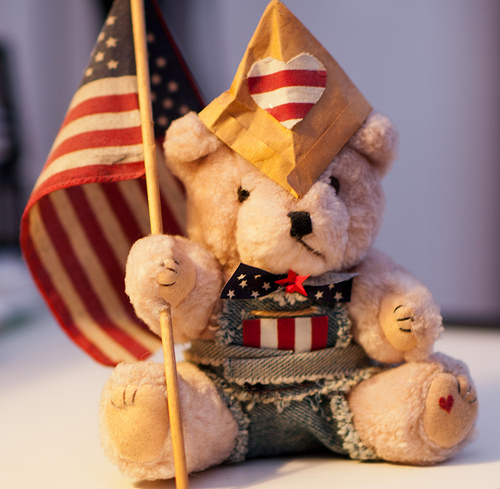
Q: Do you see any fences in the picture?
A: No, there are no fences.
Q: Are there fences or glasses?
A: No, there are no fences or glasses.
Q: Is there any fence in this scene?
A: No, there are no fences.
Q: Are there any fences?
A: No, there are no fences.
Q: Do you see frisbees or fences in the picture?
A: No, there are no fences or frisbees.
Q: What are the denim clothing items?
A: The clothing items are shorts.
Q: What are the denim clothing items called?
A: The clothing items are shorts.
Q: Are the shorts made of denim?
A: Yes, the shorts are made of denim.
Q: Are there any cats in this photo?
A: No, there are no cats.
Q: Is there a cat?
A: No, there are no cats.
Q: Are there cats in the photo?
A: No, there are no cats.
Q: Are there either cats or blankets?
A: No, there are no cats or blankets.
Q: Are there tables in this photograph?
A: Yes, there is a table.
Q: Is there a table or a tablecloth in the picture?
A: Yes, there is a table.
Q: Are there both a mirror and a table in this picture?
A: No, there is a table but no mirrors.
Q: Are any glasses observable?
A: No, there are no glasses.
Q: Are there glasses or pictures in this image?
A: No, there are no glasses or pictures.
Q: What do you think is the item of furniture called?
A: The piece of furniture is a table.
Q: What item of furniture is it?
A: The piece of furniture is a table.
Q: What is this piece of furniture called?
A: This is a table.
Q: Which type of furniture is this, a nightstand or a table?
A: This is a table.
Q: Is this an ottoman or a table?
A: This is a table.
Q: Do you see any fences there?
A: No, there are no fences.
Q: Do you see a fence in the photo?
A: No, there are no fences.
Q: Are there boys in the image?
A: No, there are no boys.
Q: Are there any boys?
A: No, there are no boys.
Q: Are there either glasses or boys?
A: No, there are no boys or glasses.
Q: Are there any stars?
A: Yes, there is a star.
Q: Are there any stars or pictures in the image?
A: Yes, there is a star.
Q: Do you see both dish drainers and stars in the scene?
A: No, there is a star but no dish drainers.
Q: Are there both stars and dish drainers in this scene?
A: No, there is a star but no dish drainers.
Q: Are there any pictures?
A: No, there are no pictures.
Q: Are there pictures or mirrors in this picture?
A: No, there are no pictures or mirrors.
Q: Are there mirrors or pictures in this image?
A: No, there are no pictures or mirrors.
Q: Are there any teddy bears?
A: Yes, there is a teddy bear.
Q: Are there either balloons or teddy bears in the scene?
A: Yes, there is a teddy bear.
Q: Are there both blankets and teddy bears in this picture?
A: No, there is a teddy bear but no blankets.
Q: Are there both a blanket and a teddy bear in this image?
A: No, there is a teddy bear but no blankets.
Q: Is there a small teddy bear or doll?
A: Yes, there is a small teddy bear.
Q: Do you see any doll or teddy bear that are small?
A: Yes, the teddy bear is small.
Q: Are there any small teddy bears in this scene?
A: Yes, there is a small teddy bear.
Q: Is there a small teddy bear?
A: Yes, there is a small teddy bear.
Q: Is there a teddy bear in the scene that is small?
A: Yes, there is a teddy bear that is small.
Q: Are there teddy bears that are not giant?
A: Yes, there is a small teddy bear.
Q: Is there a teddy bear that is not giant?
A: Yes, there is a small teddy bear.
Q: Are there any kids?
A: No, there are no kids.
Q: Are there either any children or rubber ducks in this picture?
A: No, there are no children or rubber ducks.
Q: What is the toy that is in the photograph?
A: The toy is a teddy bear.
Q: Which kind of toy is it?
A: The toy is a teddy bear.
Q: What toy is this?
A: This is a teddy bear.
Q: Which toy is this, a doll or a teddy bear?
A: This is a teddy bear.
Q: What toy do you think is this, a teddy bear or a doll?
A: This is a teddy bear.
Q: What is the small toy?
A: The toy is a teddy bear.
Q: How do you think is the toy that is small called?
A: The toy is a teddy bear.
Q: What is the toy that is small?
A: The toy is a teddy bear.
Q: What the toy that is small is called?
A: The toy is a teddy bear.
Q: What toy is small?
A: The toy is a teddy bear.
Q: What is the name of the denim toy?
A: The toy is a teddy bear.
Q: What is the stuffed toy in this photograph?
A: The toy is a teddy bear.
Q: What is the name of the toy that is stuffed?
A: The toy is a teddy bear.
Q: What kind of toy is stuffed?
A: The toy is a teddy bear.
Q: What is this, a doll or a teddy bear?
A: This is a teddy bear.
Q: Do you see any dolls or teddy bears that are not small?
A: No, there is a teddy bear but it is small.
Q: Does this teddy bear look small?
A: Yes, the teddy bear is small.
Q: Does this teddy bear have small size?
A: Yes, the teddy bear is small.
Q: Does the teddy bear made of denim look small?
A: Yes, the teddy bear is small.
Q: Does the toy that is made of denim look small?
A: Yes, the teddy bear is small.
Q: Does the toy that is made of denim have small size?
A: Yes, the teddy bear is small.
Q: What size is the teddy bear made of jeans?
A: The teddy bear is small.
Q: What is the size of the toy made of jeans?
A: The teddy bear is small.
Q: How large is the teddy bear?
A: The teddy bear is small.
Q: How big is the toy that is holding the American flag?
A: The teddy bear is small.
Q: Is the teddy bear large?
A: No, the teddy bear is small.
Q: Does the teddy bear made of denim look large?
A: No, the teddy bear is small.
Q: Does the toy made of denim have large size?
A: No, the teddy bear is small.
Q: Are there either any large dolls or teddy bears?
A: No, there is a teddy bear but it is small.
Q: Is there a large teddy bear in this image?
A: No, there is a teddy bear but it is small.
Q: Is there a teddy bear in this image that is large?
A: No, there is a teddy bear but it is small.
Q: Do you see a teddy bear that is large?
A: No, there is a teddy bear but it is small.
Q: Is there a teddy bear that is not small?
A: No, there is a teddy bear but it is small.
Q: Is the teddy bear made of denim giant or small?
A: The teddy bear is small.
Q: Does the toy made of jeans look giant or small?
A: The teddy bear is small.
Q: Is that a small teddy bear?
A: Yes, that is a small teddy bear.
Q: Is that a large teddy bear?
A: No, that is a small teddy bear.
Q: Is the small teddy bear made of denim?
A: Yes, the teddy bear is made of denim.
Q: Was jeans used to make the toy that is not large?
A: Yes, the teddy bear is made of jeans.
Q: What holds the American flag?
A: The teddy bear holds the American flag.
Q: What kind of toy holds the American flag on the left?
A: The toy is a teddy bear.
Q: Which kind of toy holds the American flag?
A: The toy is a teddy bear.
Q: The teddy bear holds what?
A: The teddy bear holds the American flag.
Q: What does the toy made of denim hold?
A: The teddy bear holds the American flag.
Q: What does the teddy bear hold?
A: The teddy bear holds the American flag.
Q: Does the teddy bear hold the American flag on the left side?
A: Yes, the teddy bear holds the American flag.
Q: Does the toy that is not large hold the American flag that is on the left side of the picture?
A: Yes, the teddy bear holds the American flag.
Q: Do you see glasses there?
A: No, there are no glasses.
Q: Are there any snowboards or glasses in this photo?
A: No, there are no glasses or snowboards.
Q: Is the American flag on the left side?
A: Yes, the American flag is on the left of the image.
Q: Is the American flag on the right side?
A: No, the American flag is on the left of the image.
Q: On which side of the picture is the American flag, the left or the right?
A: The American flag is on the left of the image.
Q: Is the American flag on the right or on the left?
A: The American flag is on the left of the image.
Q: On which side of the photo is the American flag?
A: The American flag is on the left of the image.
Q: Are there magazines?
A: No, there are no magazines.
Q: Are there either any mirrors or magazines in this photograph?
A: No, there are no magazines or mirrors.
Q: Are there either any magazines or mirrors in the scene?
A: No, there are no magazines or mirrors.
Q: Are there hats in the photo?
A: Yes, there is a hat.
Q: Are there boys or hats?
A: Yes, there is a hat.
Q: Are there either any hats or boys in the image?
A: Yes, there is a hat.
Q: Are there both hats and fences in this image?
A: No, there is a hat but no fences.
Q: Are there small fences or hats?
A: Yes, there is a small hat.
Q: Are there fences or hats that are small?
A: Yes, the hat is small.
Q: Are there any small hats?
A: Yes, there is a small hat.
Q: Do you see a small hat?
A: Yes, there is a small hat.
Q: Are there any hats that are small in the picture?
A: Yes, there is a small hat.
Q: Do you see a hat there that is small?
A: Yes, there is a hat that is small.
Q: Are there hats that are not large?
A: Yes, there is a small hat.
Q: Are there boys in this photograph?
A: No, there are no boys.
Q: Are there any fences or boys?
A: No, there are no boys or fences.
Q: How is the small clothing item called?
A: The clothing item is a hat.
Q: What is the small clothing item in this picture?
A: The clothing item is a hat.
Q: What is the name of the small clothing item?
A: The clothing item is a hat.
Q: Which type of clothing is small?
A: The clothing is a hat.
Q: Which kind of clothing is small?
A: The clothing is a hat.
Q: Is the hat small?
A: Yes, the hat is small.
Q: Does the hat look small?
A: Yes, the hat is small.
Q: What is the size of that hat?
A: The hat is small.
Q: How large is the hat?
A: The hat is small.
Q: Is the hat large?
A: No, the hat is small.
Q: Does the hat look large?
A: No, the hat is small.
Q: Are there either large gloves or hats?
A: No, there is a hat but it is small.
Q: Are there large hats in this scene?
A: No, there is a hat but it is small.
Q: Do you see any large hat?
A: No, there is a hat but it is small.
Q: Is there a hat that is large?
A: No, there is a hat but it is small.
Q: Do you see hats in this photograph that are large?
A: No, there is a hat but it is small.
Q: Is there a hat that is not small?
A: No, there is a hat but it is small.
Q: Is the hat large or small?
A: The hat is small.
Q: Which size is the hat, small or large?
A: The hat is small.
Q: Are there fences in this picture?
A: No, there are no fences.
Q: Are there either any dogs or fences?
A: No, there are no fences or dogs.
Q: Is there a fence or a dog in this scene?
A: No, there are no fences or dogs.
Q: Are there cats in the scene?
A: No, there are no cats.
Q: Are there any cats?
A: No, there are no cats.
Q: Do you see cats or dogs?
A: No, there are no cats or dogs.